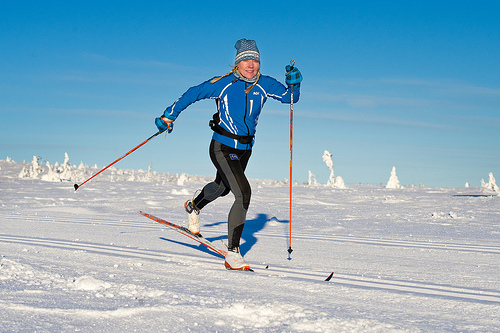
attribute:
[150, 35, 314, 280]
woman — white, skiing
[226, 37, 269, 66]
beanie — blue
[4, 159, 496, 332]
snow — above, ground, white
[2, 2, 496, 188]
sky — blue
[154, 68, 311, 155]
jacket — blue, white, warm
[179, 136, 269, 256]
pants — black, warmth, gray, grey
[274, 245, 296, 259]
globes — blak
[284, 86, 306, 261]
pole — red, orange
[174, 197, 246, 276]
shoes — ski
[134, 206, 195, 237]
brake — red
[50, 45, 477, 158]
cloud — white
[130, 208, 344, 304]
skis — red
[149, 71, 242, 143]
arm — extended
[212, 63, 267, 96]
hair — braided, blonde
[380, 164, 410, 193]
tree — background, snowcovered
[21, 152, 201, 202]
sculptures — white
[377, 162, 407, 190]
triangle — white